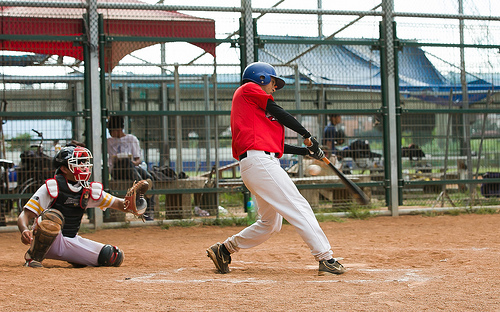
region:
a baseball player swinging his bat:
[206, 61, 369, 276]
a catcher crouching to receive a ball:
[18, 145, 150, 269]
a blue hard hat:
[239, 60, 284, 89]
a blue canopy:
[256, 40, 488, 102]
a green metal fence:
[0, 33, 499, 179]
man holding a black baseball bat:
[301, 136, 367, 202]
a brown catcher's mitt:
[121, 178, 151, 215]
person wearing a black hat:
[104, 113, 126, 128]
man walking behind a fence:
[324, 111, 343, 153]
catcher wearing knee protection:
[28, 207, 63, 264]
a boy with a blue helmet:
[238, 61, 285, 93]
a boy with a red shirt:
[226, 84, 286, 158]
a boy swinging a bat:
[206, 59, 370, 276]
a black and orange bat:
[302, 137, 370, 203]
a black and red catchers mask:
[53, 145, 95, 190]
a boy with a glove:
[122, 177, 152, 216]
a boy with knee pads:
[23, 211, 67, 272]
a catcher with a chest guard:
[40, 172, 101, 239]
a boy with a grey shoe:
[205, 237, 233, 274]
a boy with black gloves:
[303, 134, 322, 164]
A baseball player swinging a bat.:
[205, 60, 369, 282]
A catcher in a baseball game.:
[14, 142, 151, 271]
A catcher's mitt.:
[123, 177, 151, 217]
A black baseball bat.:
[305, 134, 378, 208]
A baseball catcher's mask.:
[56, 145, 94, 191]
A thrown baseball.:
[300, 159, 322, 182]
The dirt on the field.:
[404, 225, 494, 244]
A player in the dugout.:
[99, 106, 154, 180]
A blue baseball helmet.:
[239, 54, 286, 94]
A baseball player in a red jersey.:
[206, 56, 362, 285]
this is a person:
[200, 41, 360, 273]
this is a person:
[23, 136, 135, 290]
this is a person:
[301, 90, 362, 190]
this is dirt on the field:
[118, 217, 194, 305]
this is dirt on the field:
[263, 255, 303, 295]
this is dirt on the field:
[354, 225, 394, 269]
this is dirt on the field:
[71, 277, 152, 307]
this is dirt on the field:
[263, 258, 329, 292]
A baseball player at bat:
[205, 59, 370, 275]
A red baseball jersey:
[231, 84, 283, 157]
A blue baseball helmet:
[243, 60, 286, 85]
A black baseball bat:
[310, 141, 368, 205]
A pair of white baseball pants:
[222, 152, 334, 262]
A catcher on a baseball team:
[15, 141, 148, 263]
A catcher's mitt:
[125, 178, 148, 217]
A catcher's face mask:
[55, 146, 92, 183]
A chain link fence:
[0, 3, 495, 220]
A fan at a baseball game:
[104, 111, 147, 218]